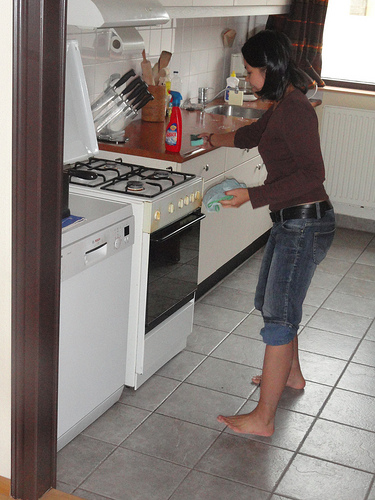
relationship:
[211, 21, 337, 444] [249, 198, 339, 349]
woman wearing pants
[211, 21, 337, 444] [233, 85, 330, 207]
woman wearing shirt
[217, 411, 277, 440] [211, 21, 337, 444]
feet belonging to woman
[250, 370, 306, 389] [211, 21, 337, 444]
foot belonging to woman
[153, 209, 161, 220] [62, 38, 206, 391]
dial controlling stove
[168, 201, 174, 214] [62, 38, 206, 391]
dial controlling stove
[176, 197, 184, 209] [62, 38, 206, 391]
dial controlling stove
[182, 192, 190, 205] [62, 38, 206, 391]
dial controlling stove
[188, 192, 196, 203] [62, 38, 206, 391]
dial controlling stove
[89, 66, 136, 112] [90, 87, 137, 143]
knife stuck in knife rack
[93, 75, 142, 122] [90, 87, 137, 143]
knife stuck in knife rack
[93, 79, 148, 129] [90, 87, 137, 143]
knife stuck in knife rack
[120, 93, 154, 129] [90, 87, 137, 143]
knife stuck in knife rack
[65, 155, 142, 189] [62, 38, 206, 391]
burner mounted on stove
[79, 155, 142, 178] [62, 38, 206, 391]
burner mounted on stove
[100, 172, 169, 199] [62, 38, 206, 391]
burner mounted on stove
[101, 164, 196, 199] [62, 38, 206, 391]
burner mounted on stove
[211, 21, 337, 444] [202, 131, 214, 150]
woman wearing bracelet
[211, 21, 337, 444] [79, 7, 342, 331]
woman cleaning kitchen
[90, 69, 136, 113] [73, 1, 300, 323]
knife in kitchen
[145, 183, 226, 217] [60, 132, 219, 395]
knobs on stove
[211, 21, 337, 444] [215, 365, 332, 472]
woman wearing no shoes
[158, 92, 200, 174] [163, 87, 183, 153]
bottle of cleaner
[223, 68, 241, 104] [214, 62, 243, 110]
bottle of soap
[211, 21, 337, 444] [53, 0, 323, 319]
woman cleaning kitchen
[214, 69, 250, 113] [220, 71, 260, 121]
bottle of cleaner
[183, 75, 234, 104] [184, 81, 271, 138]
faucet over sink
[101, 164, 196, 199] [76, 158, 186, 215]
burner on stove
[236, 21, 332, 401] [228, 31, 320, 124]
woman with hair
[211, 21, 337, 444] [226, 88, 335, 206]
woman in shirt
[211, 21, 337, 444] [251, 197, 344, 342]
woman with jeans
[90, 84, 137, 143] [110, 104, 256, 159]
knife rack on counter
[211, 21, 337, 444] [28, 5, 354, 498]
woman working kitchen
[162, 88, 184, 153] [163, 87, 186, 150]
bottle of cleaner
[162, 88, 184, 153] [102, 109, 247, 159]
bottle on counter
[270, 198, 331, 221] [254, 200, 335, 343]
belt holds pants